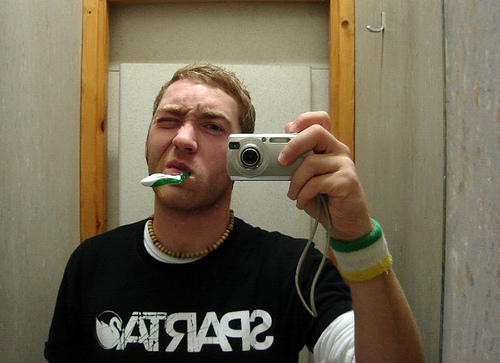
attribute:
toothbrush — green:
[147, 155, 207, 192]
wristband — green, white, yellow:
[325, 207, 392, 263]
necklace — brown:
[143, 198, 248, 271]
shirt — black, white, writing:
[78, 205, 297, 341]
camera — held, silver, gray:
[192, 111, 324, 243]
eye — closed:
[158, 108, 186, 130]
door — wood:
[140, 17, 210, 76]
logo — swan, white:
[93, 291, 137, 345]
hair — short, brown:
[179, 46, 249, 111]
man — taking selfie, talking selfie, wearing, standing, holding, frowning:
[259, 180, 383, 290]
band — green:
[331, 229, 386, 260]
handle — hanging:
[340, 7, 406, 63]